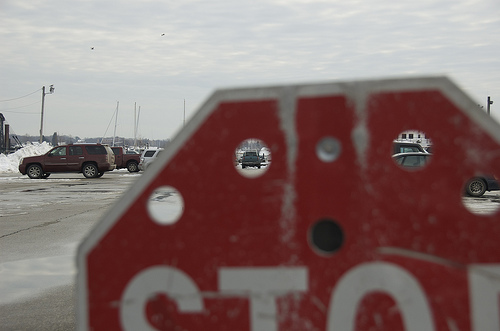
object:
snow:
[1, 141, 56, 177]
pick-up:
[108, 147, 143, 173]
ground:
[0, 172, 140, 331]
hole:
[235, 137, 272, 178]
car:
[18, 142, 116, 179]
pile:
[0, 141, 54, 174]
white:
[0, 154, 13, 169]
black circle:
[312, 218, 344, 251]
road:
[0, 156, 166, 331]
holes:
[144, 185, 185, 225]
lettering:
[120, 262, 497, 331]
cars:
[239, 150, 263, 171]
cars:
[389, 152, 500, 199]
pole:
[38, 86, 45, 144]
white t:
[217, 265, 308, 329]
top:
[221, 267, 306, 290]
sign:
[77, 72, 500, 331]